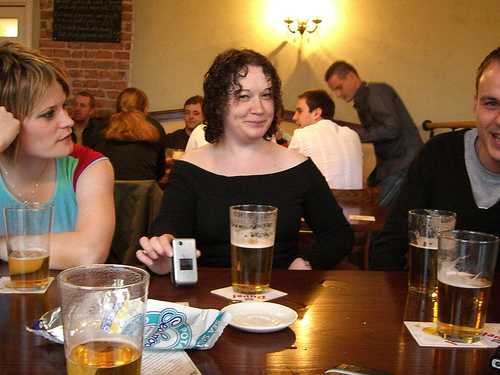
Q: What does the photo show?
A: A restaurant full of people.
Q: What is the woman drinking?
A: A beer.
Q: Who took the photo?
A: A professional photographer.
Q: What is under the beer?
A: A napkin.